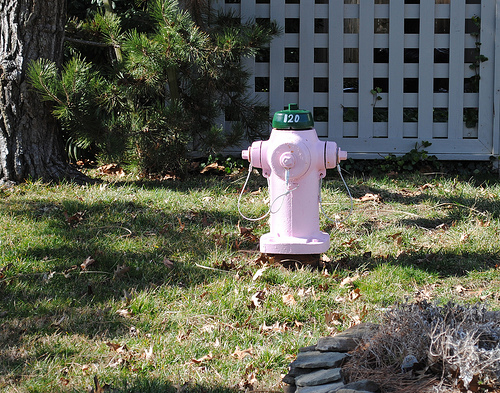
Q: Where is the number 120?
A: On the fire hydrant.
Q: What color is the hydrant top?
A: Green.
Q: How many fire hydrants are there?
A: 1.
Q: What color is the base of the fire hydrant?
A: Pink.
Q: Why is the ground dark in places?
A: Shadows.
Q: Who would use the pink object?
A: Fireman.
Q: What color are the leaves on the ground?
A: Brown.